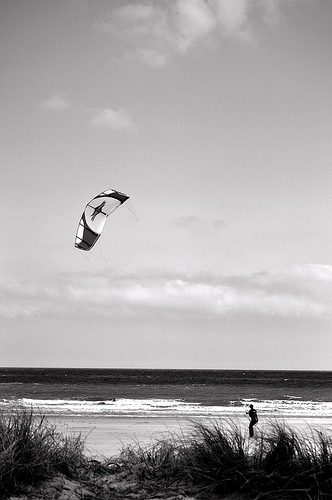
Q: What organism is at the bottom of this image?
A: Grass.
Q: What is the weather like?
A: Partly cloudy.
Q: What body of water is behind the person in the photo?
A: The ocean.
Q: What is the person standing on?
A: Sand.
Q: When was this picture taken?
A: Day time.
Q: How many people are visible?
A: One.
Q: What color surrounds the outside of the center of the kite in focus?
A: White.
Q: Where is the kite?
A: The sky.